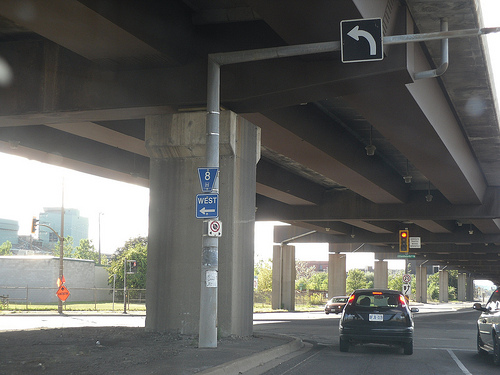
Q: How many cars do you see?
A: Three.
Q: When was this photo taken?
A: During the day.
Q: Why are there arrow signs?
A: To show where to drive.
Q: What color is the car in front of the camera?
A: Black.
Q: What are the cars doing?
A: Waiting at a light.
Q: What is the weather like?
A: Sunny.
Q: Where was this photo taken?
A: Outside near a bridge.